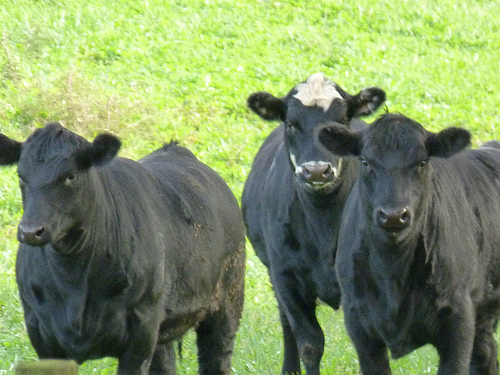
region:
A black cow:
[319, 104, 471, 313]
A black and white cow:
[222, 55, 376, 286]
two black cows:
[12, 119, 479, 312]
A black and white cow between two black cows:
[13, 75, 460, 280]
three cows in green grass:
[15, 46, 467, 329]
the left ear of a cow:
[79, 110, 148, 179]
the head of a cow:
[11, 109, 132, 297]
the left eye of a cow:
[48, 154, 85, 194]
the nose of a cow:
[20, 209, 79, 259]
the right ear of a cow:
[241, 66, 292, 143]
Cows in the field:
[0, 74, 499, 374]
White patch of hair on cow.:
[287, 72, 344, 111]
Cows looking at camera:
[2, 75, 499, 373]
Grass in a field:
[1, 4, 493, 72]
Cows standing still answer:
[0, 70, 498, 373]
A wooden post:
[14, 359, 78, 374]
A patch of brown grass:
[5, 49, 231, 146]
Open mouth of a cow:
[295, 157, 340, 191]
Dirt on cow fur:
[164, 209, 246, 374]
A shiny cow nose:
[371, 205, 414, 233]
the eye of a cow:
[357, 155, 374, 170]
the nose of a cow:
[371, 202, 413, 232]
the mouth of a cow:
[377, 222, 410, 237]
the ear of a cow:
[427, 122, 474, 163]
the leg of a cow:
[427, 308, 477, 373]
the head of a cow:
[311, 106, 475, 246]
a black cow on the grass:
[0, 113, 248, 373]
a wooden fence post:
[10, 351, 80, 373]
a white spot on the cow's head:
[290, 67, 347, 116]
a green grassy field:
[0, 0, 498, 373]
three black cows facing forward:
[19, 67, 476, 333]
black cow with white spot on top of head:
[245, 59, 361, 279]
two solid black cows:
[14, 127, 482, 292]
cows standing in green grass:
[14, 86, 496, 373]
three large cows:
[13, 65, 490, 301]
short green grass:
[44, 17, 474, 70]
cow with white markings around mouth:
[247, 59, 359, 325]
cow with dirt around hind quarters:
[17, 117, 254, 371]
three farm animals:
[8, 62, 497, 362]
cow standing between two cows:
[237, 60, 368, 350]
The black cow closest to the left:
[16, 100, 255, 365]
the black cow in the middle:
[238, 62, 383, 339]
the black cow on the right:
[308, 102, 492, 344]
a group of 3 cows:
[14, 77, 472, 350]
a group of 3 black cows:
[13, 60, 498, 358]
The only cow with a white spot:
[248, 72, 360, 194]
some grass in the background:
[72, 37, 226, 114]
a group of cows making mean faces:
[23, 50, 483, 347]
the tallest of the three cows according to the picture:
[235, 52, 377, 359]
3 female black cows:
[13, 46, 465, 339]